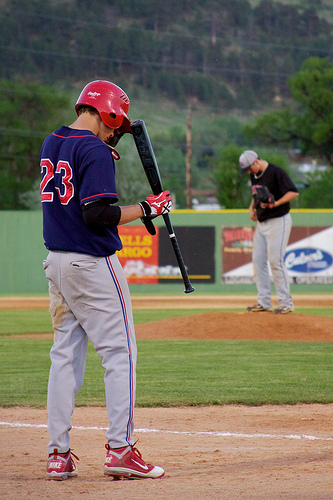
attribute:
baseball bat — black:
[128, 121, 194, 293]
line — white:
[1, 421, 332, 441]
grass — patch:
[135, 338, 331, 403]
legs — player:
[46, 290, 166, 478]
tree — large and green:
[241, 54, 331, 168]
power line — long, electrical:
[88, 16, 293, 81]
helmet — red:
[77, 82, 131, 126]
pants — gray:
[27, 255, 170, 450]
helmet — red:
[73, 79, 134, 136]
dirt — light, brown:
[211, 319, 262, 340]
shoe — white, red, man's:
[98, 448, 171, 473]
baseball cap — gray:
[229, 147, 262, 174]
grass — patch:
[1, 335, 51, 413]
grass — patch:
[159, 344, 298, 387]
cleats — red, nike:
[101, 443, 149, 473]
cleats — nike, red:
[44, 457, 68, 469]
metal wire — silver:
[3, 42, 296, 82]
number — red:
[38, 157, 73, 204]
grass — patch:
[217, 362, 252, 397]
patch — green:
[242, 358, 286, 391]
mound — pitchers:
[203, 315, 322, 335]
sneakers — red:
[46, 453, 158, 480]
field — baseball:
[137, 302, 299, 445]